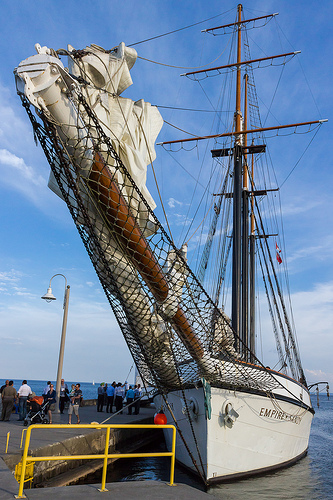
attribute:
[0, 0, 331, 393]
sky — blue, white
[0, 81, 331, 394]
clouds — white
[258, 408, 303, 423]
lettering — black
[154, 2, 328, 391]
sail — bare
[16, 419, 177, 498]
rail — yellow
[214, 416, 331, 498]
ripples — small